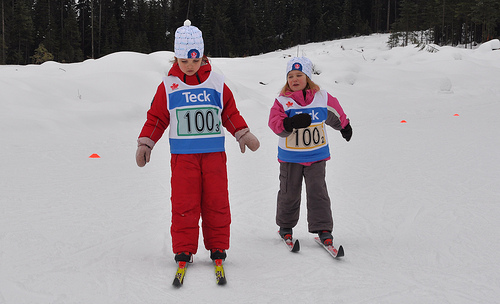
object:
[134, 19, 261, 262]
child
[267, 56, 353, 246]
child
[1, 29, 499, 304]
ground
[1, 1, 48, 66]
trees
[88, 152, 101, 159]
safety cone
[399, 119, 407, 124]
safety cone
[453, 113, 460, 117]
safety cone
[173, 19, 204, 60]
hat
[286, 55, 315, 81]
hat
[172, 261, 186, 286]
ski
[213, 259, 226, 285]
ski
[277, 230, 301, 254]
ski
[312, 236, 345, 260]
ski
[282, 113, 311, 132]
mitten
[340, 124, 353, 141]
mitten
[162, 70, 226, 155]
vest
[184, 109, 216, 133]
number 100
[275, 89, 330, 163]
vest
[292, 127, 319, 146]
number 100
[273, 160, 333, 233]
ski pants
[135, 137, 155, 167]
mitten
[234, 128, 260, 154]
mitten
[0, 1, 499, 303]
landscape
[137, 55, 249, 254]
ski suit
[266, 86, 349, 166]
coat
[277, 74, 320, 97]
hair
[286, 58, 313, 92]
head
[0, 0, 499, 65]
background